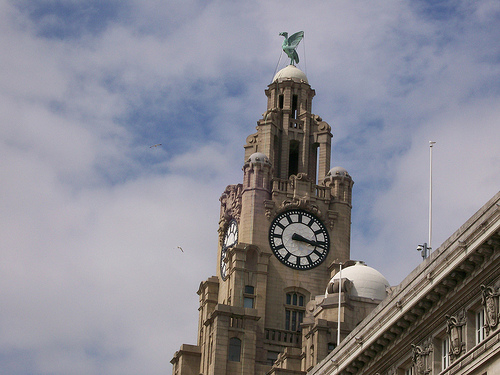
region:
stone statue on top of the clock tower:
[261, 21, 323, 81]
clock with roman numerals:
[260, 204, 338, 281]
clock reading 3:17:
[260, 197, 342, 273]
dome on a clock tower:
[254, 65, 330, 99]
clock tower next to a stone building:
[162, 19, 350, 365]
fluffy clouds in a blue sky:
[59, 101, 174, 281]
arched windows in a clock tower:
[276, 288, 308, 333]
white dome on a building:
[323, 256, 399, 313]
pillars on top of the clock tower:
[242, 108, 347, 183]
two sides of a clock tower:
[211, 199, 344, 311]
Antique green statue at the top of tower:
[271, 25, 314, 65]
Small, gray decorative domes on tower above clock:
[246, 150, 273, 168]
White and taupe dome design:
[323, 263, 391, 299]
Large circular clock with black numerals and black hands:
[268, 200, 330, 272]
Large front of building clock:
[213, 223, 240, 283]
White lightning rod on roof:
[412, 136, 439, 275]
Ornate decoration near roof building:
[403, 283, 498, 373]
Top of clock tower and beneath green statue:
[246, 66, 334, 181]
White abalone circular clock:
[266, 207, 333, 270]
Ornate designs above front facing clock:
[214, 181, 243, 218]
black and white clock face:
[279, 207, 328, 269]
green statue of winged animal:
[278, 30, 303, 65]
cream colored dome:
[271, 60, 307, 86]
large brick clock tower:
[235, 61, 338, 339]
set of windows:
[383, 296, 493, 341]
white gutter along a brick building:
[323, 246, 493, 371]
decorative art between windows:
[441, 315, 462, 355]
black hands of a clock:
[291, 230, 322, 251]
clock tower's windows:
[281, 286, 302, 327]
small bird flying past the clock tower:
[172, 240, 190, 257]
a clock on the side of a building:
[271, 210, 329, 272]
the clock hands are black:
[291, 231, 326, 251]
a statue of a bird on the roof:
[278, 28, 305, 68]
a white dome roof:
[273, 64, 311, 84]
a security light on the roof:
[415, 138, 435, 262]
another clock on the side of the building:
[218, 219, 238, 279]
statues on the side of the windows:
[443, 311, 465, 356]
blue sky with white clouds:
[0, 0, 215, 270]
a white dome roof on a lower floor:
[325, 263, 391, 299]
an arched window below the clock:
[282, 284, 309, 331]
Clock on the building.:
[211, 164, 406, 324]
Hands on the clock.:
[266, 174, 334, 254]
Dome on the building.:
[300, 180, 414, 318]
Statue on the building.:
[272, 30, 309, 73]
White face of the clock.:
[248, 207, 336, 294]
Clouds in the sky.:
[85, 140, 247, 289]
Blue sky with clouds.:
[59, 46, 252, 243]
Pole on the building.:
[370, 95, 465, 282]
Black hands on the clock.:
[265, 175, 325, 291]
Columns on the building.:
[193, 277, 242, 359]